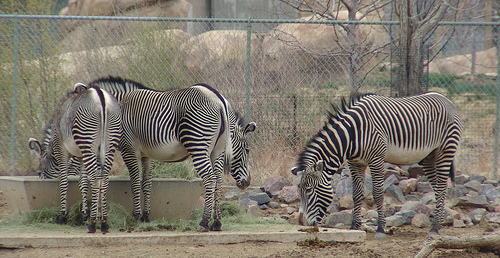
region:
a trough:
[0, 176, 207, 224]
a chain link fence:
[1, 12, 498, 194]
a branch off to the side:
[413, 234, 498, 256]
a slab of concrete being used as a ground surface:
[0, 220, 368, 247]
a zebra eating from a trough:
[29, 85, 121, 235]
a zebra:
[87, 76, 232, 231]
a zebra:
[207, 97, 259, 187]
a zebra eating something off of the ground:
[288, 89, 461, 233]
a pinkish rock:
[406, 209, 433, 229]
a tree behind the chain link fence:
[370, 0, 452, 97]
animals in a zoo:
[7, 3, 494, 248]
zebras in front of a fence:
[18, 50, 473, 250]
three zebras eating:
[28, 71, 494, 223]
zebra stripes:
[366, 102, 446, 140]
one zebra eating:
[283, 73, 483, 240]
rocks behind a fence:
[166, 0, 396, 100]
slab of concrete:
[0, 216, 372, 251]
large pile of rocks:
[334, 163, 491, 235]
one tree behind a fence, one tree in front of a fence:
[288, 1, 475, 96]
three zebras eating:
[24, 51, 278, 240]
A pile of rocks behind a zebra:
[301, 151, 494, 220]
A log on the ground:
[407, 234, 492, 252]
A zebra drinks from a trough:
[12, 92, 86, 200]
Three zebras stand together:
[14, 80, 256, 238]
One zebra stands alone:
[294, 81, 467, 256]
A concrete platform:
[19, 209, 378, 243]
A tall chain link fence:
[156, 11, 354, 135]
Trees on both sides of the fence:
[333, 3, 498, 101]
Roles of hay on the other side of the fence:
[200, 8, 377, 98]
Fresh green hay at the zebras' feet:
[67, 193, 187, 236]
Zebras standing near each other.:
[52, 1, 479, 240]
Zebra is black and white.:
[33, 82, 166, 224]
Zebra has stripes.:
[313, 74, 448, 230]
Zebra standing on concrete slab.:
[63, 202, 263, 255]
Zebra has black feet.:
[53, 210, 140, 252]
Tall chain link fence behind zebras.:
[235, 21, 370, 145]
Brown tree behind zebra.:
[386, 5, 453, 92]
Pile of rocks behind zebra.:
[331, 151, 466, 247]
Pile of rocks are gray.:
[278, 148, 466, 255]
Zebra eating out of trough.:
[4, 140, 121, 255]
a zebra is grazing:
[283, 87, 460, 244]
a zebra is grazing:
[32, 82, 124, 226]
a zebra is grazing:
[95, 75, 229, 239]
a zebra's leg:
[187, 129, 214, 229]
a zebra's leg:
[368, 155, 388, 228]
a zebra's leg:
[348, 162, 365, 234]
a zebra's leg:
[431, 148, 453, 240]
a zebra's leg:
[121, 152, 145, 221]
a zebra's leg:
[141, 157, 154, 217]